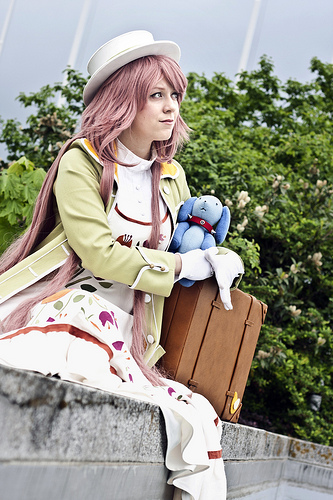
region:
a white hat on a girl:
[78, 31, 190, 83]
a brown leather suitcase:
[165, 274, 279, 411]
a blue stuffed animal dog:
[172, 190, 239, 277]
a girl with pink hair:
[84, 56, 210, 153]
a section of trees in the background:
[262, 131, 324, 358]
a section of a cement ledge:
[24, 409, 122, 481]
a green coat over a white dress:
[36, 152, 167, 366]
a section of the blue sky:
[25, 9, 59, 54]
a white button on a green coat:
[162, 181, 171, 197]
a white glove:
[176, 244, 215, 284]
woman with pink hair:
[82, 20, 231, 155]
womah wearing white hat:
[60, 15, 216, 112]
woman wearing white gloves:
[151, 237, 205, 282]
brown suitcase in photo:
[163, 252, 263, 428]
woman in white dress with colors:
[70, 132, 199, 433]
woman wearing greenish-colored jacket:
[39, 139, 181, 304]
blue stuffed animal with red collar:
[183, 152, 230, 277]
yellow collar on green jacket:
[88, 132, 187, 187]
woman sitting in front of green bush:
[14, 39, 323, 379]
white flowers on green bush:
[216, 144, 331, 312]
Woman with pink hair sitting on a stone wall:
[2, 54, 244, 498]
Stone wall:
[0, 363, 332, 498]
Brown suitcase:
[157, 275, 268, 424]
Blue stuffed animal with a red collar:
[171, 194, 230, 287]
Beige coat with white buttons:
[0, 137, 192, 369]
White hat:
[82, 28, 181, 107]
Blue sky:
[0, 0, 332, 166]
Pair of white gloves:
[174, 245, 244, 310]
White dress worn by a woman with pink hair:
[0, 136, 227, 499]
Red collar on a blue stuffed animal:
[185, 213, 214, 234]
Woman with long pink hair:
[19, 33, 266, 389]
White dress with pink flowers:
[32, 200, 225, 460]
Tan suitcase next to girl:
[161, 274, 271, 439]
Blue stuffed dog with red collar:
[159, 181, 243, 298]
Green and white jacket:
[36, 123, 210, 408]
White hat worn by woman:
[65, 23, 200, 101]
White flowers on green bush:
[226, 185, 332, 348]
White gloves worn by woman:
[151, 239, 247, 308]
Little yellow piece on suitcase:
[226, 387, 241, 431]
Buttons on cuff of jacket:
[150, 260, 167, 276]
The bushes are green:
[186, 67, 328, 217]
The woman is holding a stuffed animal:
[157, 173, 247, 292]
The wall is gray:
[31, 404, 220, 499]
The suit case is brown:
[169, 276, 271, 428]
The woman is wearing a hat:
[49, 33, 222, 124]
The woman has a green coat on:
[19, 141, 214, 303]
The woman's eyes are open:
[64, 67, 198, 146]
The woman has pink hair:
[46, 72, 231, 168]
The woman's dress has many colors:
[6, 266, 224, 471]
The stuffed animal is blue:
[138, 180, 304, 310]